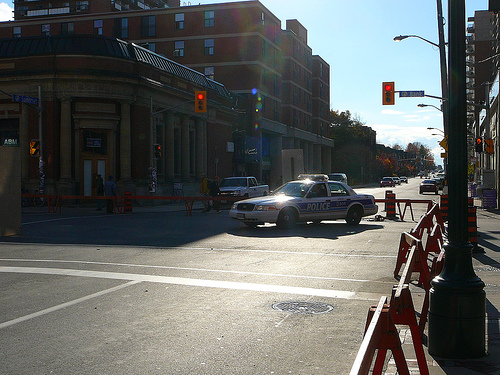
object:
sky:
[168, 0, 486, 149]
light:
[193, 86, 206, 112]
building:
[0, 2, 333, 199]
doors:
[84, 154, 109, 197]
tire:
[277, 206, 298, 229]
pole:
[426, 1, 485, 364]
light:
[381, 81, 397, 105]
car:
[229, 177, 377, 227]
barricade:
[350, 191, 443, 372]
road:
[0, 166, 500, 375]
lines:
[0, 278, 142, 332]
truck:
[216, 175, 271, 200]